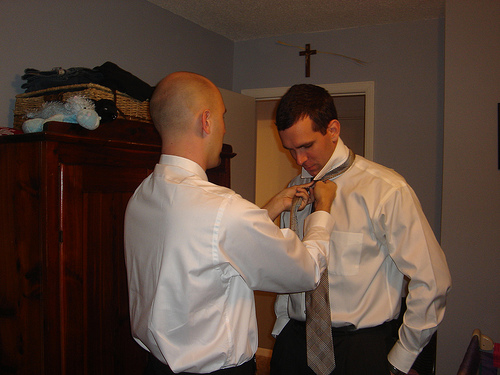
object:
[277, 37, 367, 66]
palm frond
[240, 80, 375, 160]
frame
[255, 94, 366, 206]
doorway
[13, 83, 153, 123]
basket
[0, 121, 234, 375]
armoire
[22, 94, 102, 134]
stuffed animal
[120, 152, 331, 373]
dress shirt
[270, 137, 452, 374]
dress shirt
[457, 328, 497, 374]
playpen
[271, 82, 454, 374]
man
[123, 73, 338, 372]
man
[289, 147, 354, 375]
necktie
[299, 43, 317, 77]
cross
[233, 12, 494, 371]
wall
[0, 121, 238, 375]
shelf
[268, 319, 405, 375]
pants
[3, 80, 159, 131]
shelf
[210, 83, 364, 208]
door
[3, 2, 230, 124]
wall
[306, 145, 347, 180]
neck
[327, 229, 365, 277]
pocket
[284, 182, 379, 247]
chest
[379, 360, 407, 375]
hand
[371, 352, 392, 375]
pocket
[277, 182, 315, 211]
hands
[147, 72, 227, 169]
head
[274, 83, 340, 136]
hair